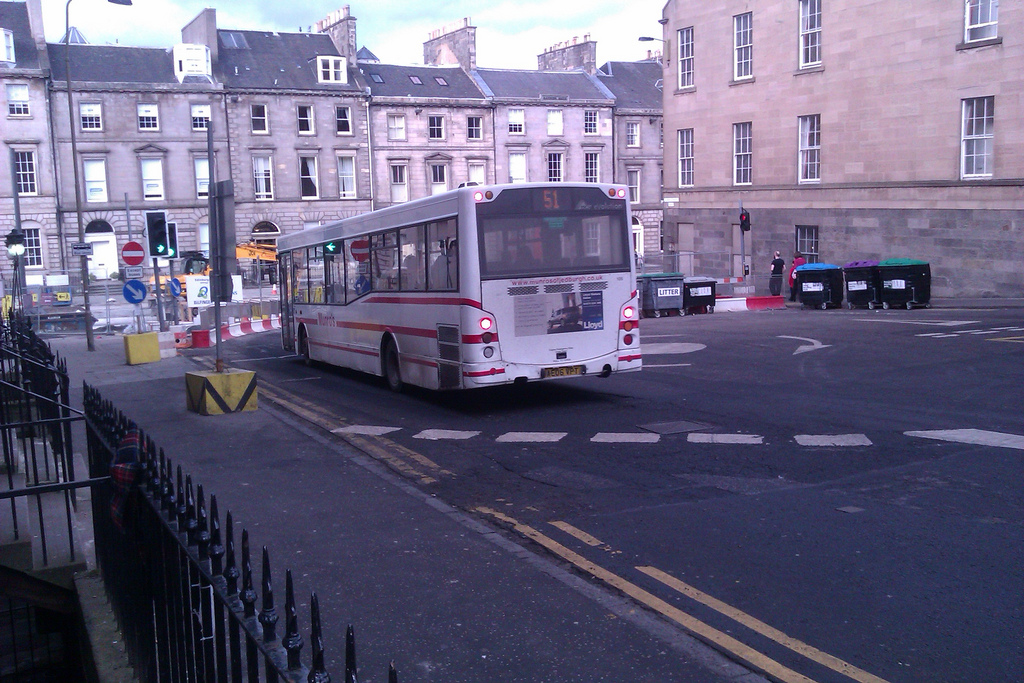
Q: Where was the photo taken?
A: On a city street.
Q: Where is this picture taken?
A: On the street.